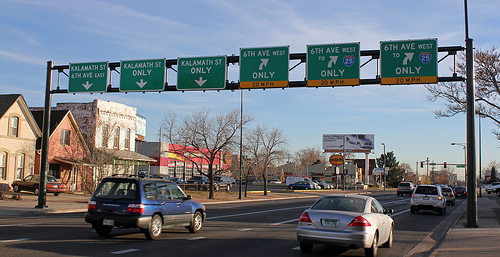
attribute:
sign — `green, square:
[66, 63, 108, 93]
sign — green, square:
[122, 62, 162, 91]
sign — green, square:
[174, 54, 226, 93]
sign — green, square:
[241, 46, 288, 90]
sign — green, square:
[308, 46, 358, 88]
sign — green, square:
[382, 39, 439, 85]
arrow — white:
[81, 79, 97, 89]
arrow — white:
[132, 76, 154, 90]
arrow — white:
[189, 74, 214, 86]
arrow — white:
[255, 53, 274, 71]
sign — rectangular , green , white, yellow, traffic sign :
[321, 54, 345, 74]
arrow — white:
[397, 49, 416, 69]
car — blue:
[71, 173, 215, 240]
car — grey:
[295, 186, 391, 256]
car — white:
[406, 178, 452, 220]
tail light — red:
[85, 203, 103, 210]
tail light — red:
[127, 205, 147, 217]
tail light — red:
[297, 209, 320, 224]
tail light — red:
[352, 211, 372, 230]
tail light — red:
[408, 192, 420, 201]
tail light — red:
[437, 192, 446, 206]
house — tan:
[0, 94, 38, 191]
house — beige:
[41, 105, 88, 192]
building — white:
[55, 99, 143, 176]